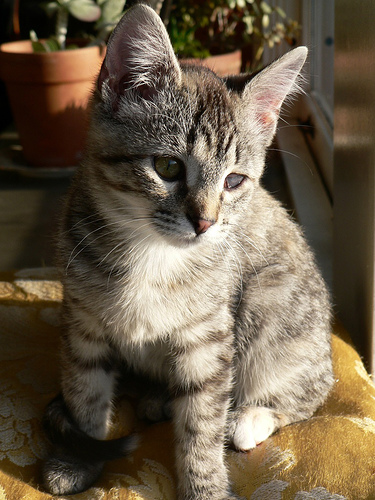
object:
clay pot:
[1, 35, 109, 168]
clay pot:
[177, 49, 242, 80]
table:
[1, 141, 290, 269]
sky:
[301, 0, 345, 150]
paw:
[38, 453, 100, 497]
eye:
[150, 150, 186, 183]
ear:
[93, 4, 183, 126]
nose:
[194, 219, 212, 235]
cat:
[42, 4, 335, 500]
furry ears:
[121, 20, 165, 94]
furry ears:
[247, 66, 307, 142]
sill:
[272, 113, 335, 301]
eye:
[224, 171, 252, 190]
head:
[92, 1, 310, 250]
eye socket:
[225, 173, 244, 193]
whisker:
[221, 229, 275, 312]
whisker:
[57, 206, 149, 288]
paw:
[221, 405, 277, 451]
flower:
[0, 398, 56, 467]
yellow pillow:
[0, 280, 375, 500]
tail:
[40, 389, 142, 463]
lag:
[56, 319, 117, 466]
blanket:
[0, 278, 374, 498]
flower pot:
[0, 38, 107, 170]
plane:
[71, 3, 310, 251]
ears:
[227, 44, 310, 147]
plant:
[25, 0, 103, 49]